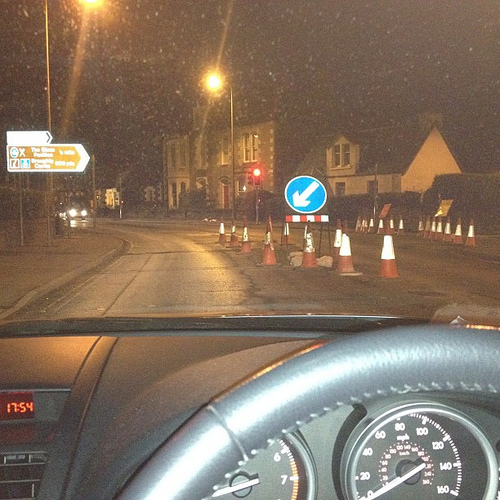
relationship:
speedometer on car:
[337, 407, 492, 499] [8, 107, 494, 495]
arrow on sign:
[291, 192, 318, 208] [281, 170, 331, 212]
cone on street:
[380, 226, 402, 278] [124, 216, 491, 318]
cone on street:
[214, 215, 226, 249] [124, 216, 491, 318]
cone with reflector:
[330, 227, 364, 279] [343, 236, 352, 257]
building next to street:
[162, 116, 277, 215] [124, 216, 491, 318]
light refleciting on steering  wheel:
[200, 436, 233, 459] [303, 330, 482, 390]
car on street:
[63, 203, 95, 225] [124, 216, 491, 318]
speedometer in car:
[337, 407, 492, 499] [8, 107, 494, 495]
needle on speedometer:
[406, 466, 423, 478] [337, 407, 492, 499]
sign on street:
[6, 144, 93, 171] [124, 216, 491, 318]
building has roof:
[313, 118, 458, 203] [366, 124, 423, 156]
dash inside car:
[14, 333, 282, 369] [8, 107, 494, 495]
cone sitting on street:
[242, 216, 258, 256] [124, 216, 491, 318]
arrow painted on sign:
[291, 192, 318, 208] [281, 170, 331, 212]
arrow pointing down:
[291, 192, 318, 208] [278, 220, 284, 232]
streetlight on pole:
[200, 65, 227, 96] [225, 88, 239, 222]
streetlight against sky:
[73, 1, 107, 13] [6, 4, 499, 112]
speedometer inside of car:
[337, 407, 492, 499] [8, 107, 494, 495]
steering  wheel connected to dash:
[303, 330, 482, 390] [14, 333, 282, 369]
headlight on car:
[82, 211, 88, 216] [63, 203, 95, 225]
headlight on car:
[67, 210, 77, 219] [63, 203, 95, 225]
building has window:
[162, 116, 277, 215] [243, 134, 257, 159]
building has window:
[162, 116, 277, 215] [171, 145, 181, 176]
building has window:
[162, 116, 277, 215] [168, 186, 178, 209]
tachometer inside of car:
[217, 447, 312, 499] [8, 107, 494, 495]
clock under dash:
[2, 390, 36, 419] [14, 333, 282, 369]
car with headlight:
[63, 203, 95, 225] [82, 211, 88, 216]